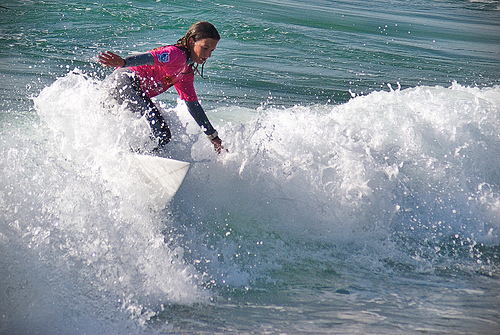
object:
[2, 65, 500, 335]
splash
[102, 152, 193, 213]
surfboard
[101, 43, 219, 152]
wetsuit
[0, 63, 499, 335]
foam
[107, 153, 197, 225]
surfboard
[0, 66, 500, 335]
wave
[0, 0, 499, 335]
water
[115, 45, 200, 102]
shirt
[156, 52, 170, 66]
logo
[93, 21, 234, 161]
surfer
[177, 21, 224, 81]
hair